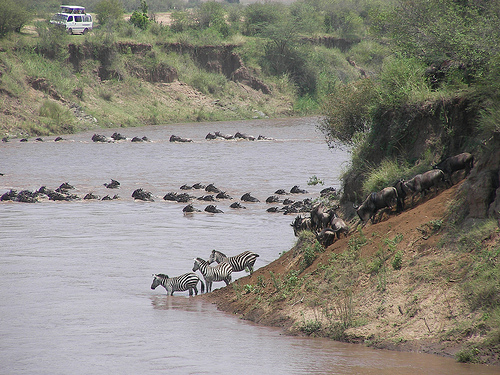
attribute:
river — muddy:
[0, 105, 452, 372]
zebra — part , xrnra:
[183, 269, 200, 289]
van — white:
[48, 2, 99, 34]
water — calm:
[5, 204, 147, 374]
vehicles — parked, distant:
[50, 5, 95, 37]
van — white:
[48, 9, 95, 35]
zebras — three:
[148, 247, 262, 298]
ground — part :
[332, 232, 385, 317]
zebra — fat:
[149, 263, 202, 304]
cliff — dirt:
[0, 37, 392, 125]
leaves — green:
[324, 66, 440, 144]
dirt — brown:
[213, 176, 498, 326]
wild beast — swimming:
[82, 187, 100, 204]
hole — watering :
[5, 114, 474, 372]